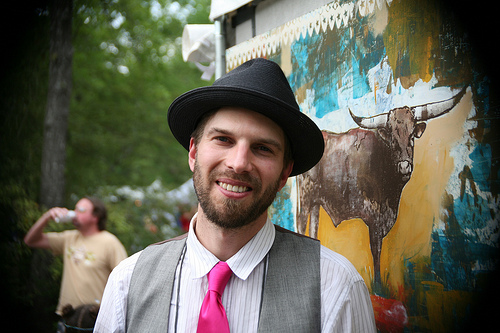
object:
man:
[15, 193, 140, 327]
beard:
[190, 155, 285, 229]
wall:
[222, 1, 498, 328]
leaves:
[70, 56, 146, 159]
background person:
[23, 195, 128, 330]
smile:
[203, 172, 266, 207]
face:
[196, 107, 287, 226]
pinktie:
[196, 260, 233, 331]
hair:
[87, 195, 109, 233]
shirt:
[46, 230, 128, 315]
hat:
[158, 57, 331, 179]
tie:
[195, 260, 232, 331]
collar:
[181, 212, 278, 274]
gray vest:
[128, 222, 329, 333]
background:
[1, 0, 500, 332]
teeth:
[216, 182, 252, 194]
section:
[220, 0, 333, 45]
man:
[93, 55, 375, 333]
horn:
[342, 104, 387, 135]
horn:
[414, 85, 469, 125]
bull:
[295, 83, 473, 285]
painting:
[270, 0, 497, 330]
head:
[184, 98, 300, 228]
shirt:
[90, 213, 384, 331]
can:
[55, 211, 76, 223]